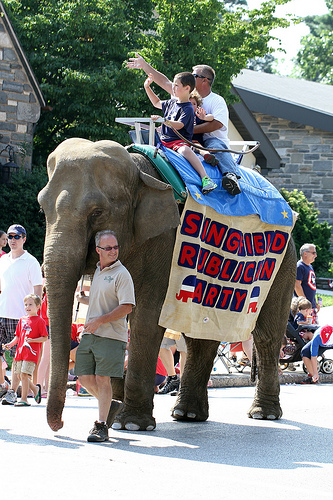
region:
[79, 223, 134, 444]
the man leading the elephant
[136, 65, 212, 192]
the boy in the front on top the elephant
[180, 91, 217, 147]
the baby int he middle on top the elephant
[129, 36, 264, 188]
the man in back on top the elephant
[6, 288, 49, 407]
the little boy wearing a red shirt by the elephant's trunk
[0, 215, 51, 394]
a man wearing a blue hat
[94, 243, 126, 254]
the glasses on the man leading the elephant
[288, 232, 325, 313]
a man wearing a blue shirt with a yellow star in the middle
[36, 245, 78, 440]
the nose of the elephant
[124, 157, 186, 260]
the elephant's left ear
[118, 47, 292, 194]
Three people on elephant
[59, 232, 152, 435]
Man leading elephant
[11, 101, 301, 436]
There is an elephant for an event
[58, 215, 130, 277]
Man is wearing sunglasses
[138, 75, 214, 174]
Two kids on elephant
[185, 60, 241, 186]
One dad on elephant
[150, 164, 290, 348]
There is a banner on the elephant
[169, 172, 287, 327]
Banner is for republican party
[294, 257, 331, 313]
Man in background has captain america shirt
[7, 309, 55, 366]
Little kid has red shirt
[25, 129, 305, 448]
an elephant on a parade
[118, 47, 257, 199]
a man and two kids sits on an elephant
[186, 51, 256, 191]
man wears white shirt and blue jeans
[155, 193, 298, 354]
a banner on elephant says "SIngfield Republican Party"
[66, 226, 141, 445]
man walking near an elephant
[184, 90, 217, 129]
a child raising his hand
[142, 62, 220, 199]
boy wears a blue shirt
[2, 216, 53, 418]
man and a boy walking near an elephant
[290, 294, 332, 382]
kid sits in a stroller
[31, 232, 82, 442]
long trunk of elephant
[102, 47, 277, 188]
Three people are on the elephant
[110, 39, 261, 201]
People riding elephant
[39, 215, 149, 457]
Man is guiding the elephant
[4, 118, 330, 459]
Elephant has republican party sign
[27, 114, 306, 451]
The elephant is large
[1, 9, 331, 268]
Two stone buildings in background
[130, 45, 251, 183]
Two kids and one adult on the elephant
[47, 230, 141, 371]
Guiding man is smiling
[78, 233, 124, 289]
Man has sunglasses on face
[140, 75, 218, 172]
Kid has navy blue shirt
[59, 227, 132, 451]
man next to an elephant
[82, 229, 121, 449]
man wearing a beige shirt and shorts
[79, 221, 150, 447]
man wearing sun shades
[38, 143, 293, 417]
large gray elephant with people riding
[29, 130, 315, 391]
elephant with a bannner on the side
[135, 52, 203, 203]
boy riding a elephant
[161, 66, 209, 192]
boy wearng a blue shirt and shorts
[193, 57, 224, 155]
man riding an elephant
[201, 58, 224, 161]
man wearing a white shirt and jeans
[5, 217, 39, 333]
man wearing a white shirt and shorts